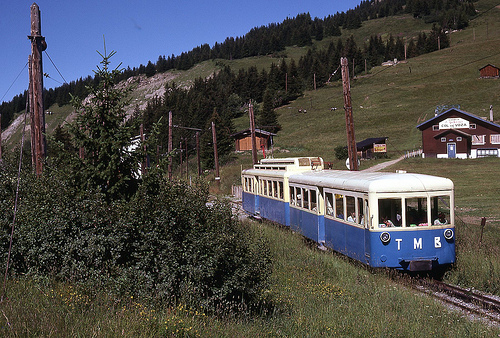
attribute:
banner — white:
[437, 116, 467, 130]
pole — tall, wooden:
[304, 35, 369, 151]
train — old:
[241, 155, 457, 271]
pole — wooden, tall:
[244, 102, 259, 165]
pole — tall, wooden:
[340, 53, 360, 170]